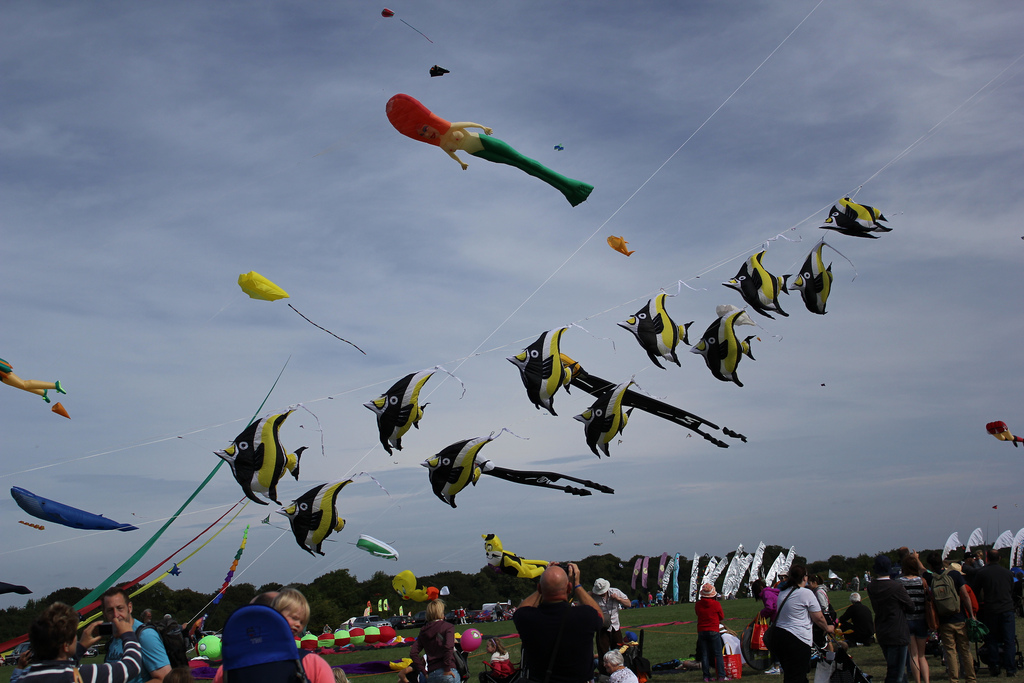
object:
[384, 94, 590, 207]
mermaid kite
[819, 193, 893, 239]
kite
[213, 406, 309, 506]
kite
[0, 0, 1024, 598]
sky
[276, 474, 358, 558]
kite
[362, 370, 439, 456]
kite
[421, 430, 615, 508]
kite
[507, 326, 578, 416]
kite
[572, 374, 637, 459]
kite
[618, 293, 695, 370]
kite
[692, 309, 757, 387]
kite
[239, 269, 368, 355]
kite